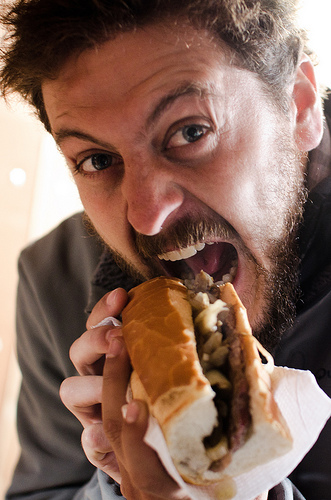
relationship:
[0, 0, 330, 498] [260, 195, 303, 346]
guy has beard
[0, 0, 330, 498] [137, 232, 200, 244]
guy has mustache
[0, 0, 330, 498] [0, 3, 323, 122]
guy has hair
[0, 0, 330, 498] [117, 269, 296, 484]
guy holding sandwich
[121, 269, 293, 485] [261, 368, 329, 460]
cheesesteak on paper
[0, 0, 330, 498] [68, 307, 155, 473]
guy has hand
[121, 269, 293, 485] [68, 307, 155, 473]
cheesesteak on hand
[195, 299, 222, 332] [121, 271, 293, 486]
cheese on cheesesteak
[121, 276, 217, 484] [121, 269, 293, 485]
bread roll on cheesesteak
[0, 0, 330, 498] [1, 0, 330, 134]
guy has hair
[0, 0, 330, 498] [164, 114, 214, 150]
guy has blue eyes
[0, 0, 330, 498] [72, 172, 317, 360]
guy has beard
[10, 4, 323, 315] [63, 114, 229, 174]
man's face has blue eyes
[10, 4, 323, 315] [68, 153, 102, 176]
man's face has long eyelashes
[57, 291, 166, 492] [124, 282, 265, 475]
hands hold sandwich